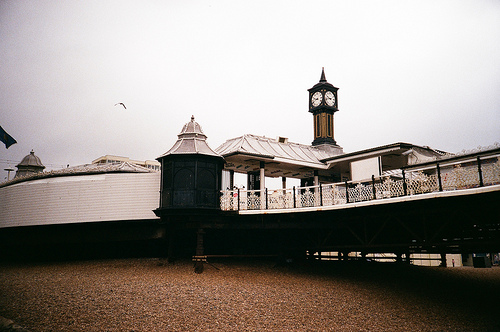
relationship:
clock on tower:
[310, 91, 324, 108] [308, 63, 342, 145]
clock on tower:
[324, 90, 336, 107] [308, 63, 342, 145]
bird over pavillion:
[109, 102, 127, 110] [4, 148, 163, 256]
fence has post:
[221, 155, 500, 211] [291, 186, 298, 211]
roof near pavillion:
[212, 134, 333, 179] [4, 148, 163, 256]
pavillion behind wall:
[4, 148, 163, 256] [5, 171, 166, 225]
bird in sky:
[109, 102, 127, 110] [53, 36, 207, 97]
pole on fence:
[236, 190, 243, 212] [221, 155, 500, 211]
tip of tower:
[320, 64, 326, 84] [308, 63, 342, 145]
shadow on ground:
[266, 254, 498, 331] [9, 265, 408, 331]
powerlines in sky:
[1, 155, 22, 167] [53, 36, 207, 97]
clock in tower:
[310, 91, 324, 108] [308, 63, 342, 145]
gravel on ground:
[223, 272, 253, 284] [9, 265, 408, 331]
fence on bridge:
[221, 155, 500, 211] [234, 186, 498, 257]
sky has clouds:
[53, 36, 207, 97] [354, 37, 476, 120]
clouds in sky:
[354, 37, 476, 120] [53, 36, 207, 97]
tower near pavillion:
[308, 63, 342, 145] [4, 153, 163, 256]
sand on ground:
[331, 303, 382, 329] [9, 265, 408, 331]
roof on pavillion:
[212, 136, 333, 179] [4, 153, 163, 256]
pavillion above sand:
[4, 148, 163, 256] [331, 303, 382, 329]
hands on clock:
[312, 96, 319, 105] [310, 91, 324, 108]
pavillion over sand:
[4, 148, 163, 256] [331, 303, 382, 329]